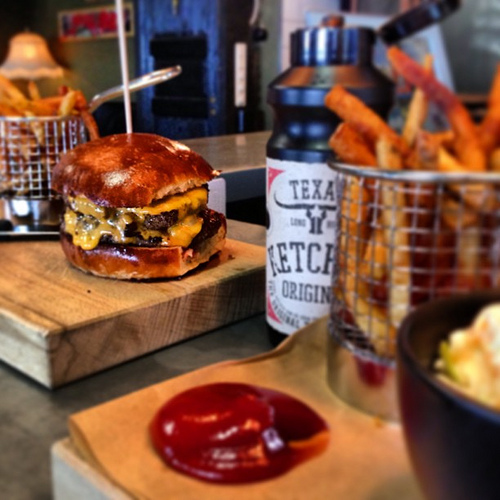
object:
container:
[326, 160, 497, 419]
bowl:
[394, 289, 498, 496]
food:
[430, 292, 499, 407]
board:
[1, 200, 268, 390]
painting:
[56, 5, 136, 43]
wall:
[2, 2, 499, 117]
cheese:
[61, 205, 99, 239]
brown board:
[41, 435, 127, 498]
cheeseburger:
[49, 132, 228, 282]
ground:
[55, 378, 107, 423]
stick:
[111, 4, 137, 136]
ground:
[0, 393, 50, 500]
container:
[0, 111, 92, 239]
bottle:
[259, 25, 367, 347]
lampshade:
[1, 30, 66, 80]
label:
[263, 152, 343, 336]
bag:
[67, 307, 499, 497]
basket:
[0, 112, 89, 236]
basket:
[323, 151, 498, 426]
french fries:
[321, 47, 498, 363]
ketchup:
[142, 370, 332, 488]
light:
[22, 44, 35, 57]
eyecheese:
[64, 189, 207, 247]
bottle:
[262, 25, 396, 352]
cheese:
[168, 213, 202, 250]